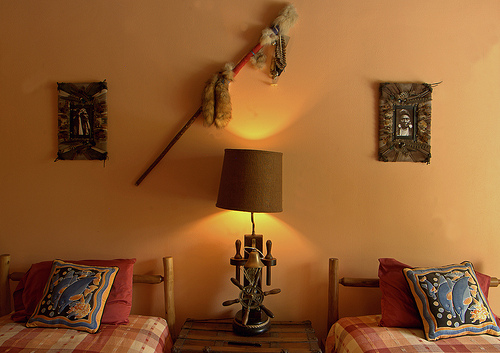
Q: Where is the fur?
A: On stick.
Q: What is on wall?
A: Stick.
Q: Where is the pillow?
A: On bed.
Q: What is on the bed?
A: Two pillows.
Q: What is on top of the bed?
A: Pillows.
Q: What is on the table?
A: A tall lamp.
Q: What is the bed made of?
A: Wood.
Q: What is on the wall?
A: Two pictures.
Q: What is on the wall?
A: American Indian artwork.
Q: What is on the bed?
A: Two pillows.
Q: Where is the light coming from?
A: The lamp.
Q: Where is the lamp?
A: Between the beds.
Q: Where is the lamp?
A: On the stand.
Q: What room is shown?
A: Bedroom.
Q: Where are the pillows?
A: Bed.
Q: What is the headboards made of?
A: Wood.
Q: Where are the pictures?
A: On the wall.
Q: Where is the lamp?
A: On the table.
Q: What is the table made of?
A: Wood.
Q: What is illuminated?
A: Lamp.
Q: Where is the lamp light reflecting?
A: Wall.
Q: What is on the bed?
A: Comforter.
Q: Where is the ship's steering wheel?
A: On the lamp.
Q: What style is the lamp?
A: Nautical.